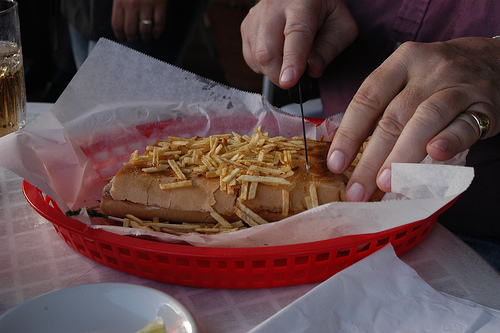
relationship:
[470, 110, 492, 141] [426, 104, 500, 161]
ring on finger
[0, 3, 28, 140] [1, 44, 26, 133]
glass has liquid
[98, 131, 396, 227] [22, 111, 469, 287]
food in basket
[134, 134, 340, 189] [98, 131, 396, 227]
fries are on sandwich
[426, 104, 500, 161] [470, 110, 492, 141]
finger has a ring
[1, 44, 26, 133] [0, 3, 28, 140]
beer in glass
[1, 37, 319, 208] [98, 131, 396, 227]
paper under sandwich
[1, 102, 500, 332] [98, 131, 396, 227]
table under sandwich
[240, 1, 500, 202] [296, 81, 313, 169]
person holding knife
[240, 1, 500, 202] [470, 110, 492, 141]
person wearing a ring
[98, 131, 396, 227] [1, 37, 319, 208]
food on paper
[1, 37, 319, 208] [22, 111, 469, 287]
paper in basket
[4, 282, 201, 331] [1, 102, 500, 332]
bowl on table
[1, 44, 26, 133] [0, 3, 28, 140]
liquid in glass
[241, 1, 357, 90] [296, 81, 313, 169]
hand has a knife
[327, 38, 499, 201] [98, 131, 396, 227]
hand holding sandwich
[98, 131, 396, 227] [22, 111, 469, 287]
sandwich in basket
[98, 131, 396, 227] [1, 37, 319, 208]
sandwich on paper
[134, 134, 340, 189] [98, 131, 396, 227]
chips are on sandwich